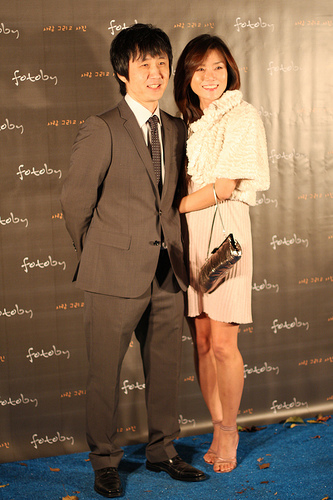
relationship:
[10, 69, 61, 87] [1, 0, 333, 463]
word on front of wall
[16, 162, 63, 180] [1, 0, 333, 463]
word on front of wall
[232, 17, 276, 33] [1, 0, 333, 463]
word on front of wall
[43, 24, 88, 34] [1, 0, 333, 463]
word on front of wall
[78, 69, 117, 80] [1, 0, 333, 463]
word on front of wall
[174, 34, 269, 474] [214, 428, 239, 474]
woman has foot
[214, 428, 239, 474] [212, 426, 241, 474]
foot wearing shoe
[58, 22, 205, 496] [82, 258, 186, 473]
man wearing pants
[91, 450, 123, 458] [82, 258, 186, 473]
wrinkle on top of pants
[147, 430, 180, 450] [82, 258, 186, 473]
wrinkle on top of pants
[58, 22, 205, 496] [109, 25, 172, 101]
man has head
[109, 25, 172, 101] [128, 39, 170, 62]
head has bangs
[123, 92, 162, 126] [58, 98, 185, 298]
collar over top of jacket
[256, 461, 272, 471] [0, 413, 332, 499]
leaf on top of floor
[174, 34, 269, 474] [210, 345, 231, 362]
woman has knee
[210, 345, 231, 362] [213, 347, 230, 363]
knee has muscle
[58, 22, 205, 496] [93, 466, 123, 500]
man wearing shoe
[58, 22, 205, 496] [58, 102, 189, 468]
man dressed in suit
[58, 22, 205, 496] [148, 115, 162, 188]
man wearing tie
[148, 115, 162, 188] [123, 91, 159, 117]
tie around neck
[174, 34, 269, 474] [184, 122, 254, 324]
woman wearing dress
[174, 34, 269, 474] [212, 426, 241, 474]
woman wearing shoe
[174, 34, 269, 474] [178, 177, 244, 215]
woman with arm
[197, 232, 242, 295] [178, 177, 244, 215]
purse hanging from arm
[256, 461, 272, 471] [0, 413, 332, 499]
leaf on top of carpet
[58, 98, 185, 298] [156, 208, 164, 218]
jacket has button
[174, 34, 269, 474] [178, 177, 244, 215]
woman has arm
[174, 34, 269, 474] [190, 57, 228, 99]
woman has face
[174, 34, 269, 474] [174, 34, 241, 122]
woman has hair